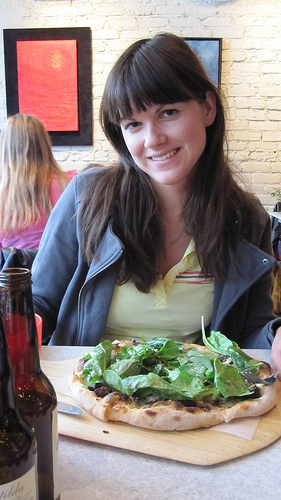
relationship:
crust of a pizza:
[69, 337, 276, 435] [68, 336, 277, 431]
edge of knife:
[56, 400, 82, 410] [54, 399, 84, 417]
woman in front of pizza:
[27, 27, 279, 372] [68, 336, 277, 431]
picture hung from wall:
[1, 25, 96, 152] [1, 0, 279, 220]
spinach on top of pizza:
[81, 315, 277, 404] [68, 336, 277, 431]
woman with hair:
[27, 27, 279, 372] [74, 33, 250, 296]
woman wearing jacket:
[27, 27, 279, 372] [29, 166, 280, 352]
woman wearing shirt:
[27, 27, 279, 372] [98, 230, 215, 346]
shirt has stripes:
[98, 230, 215, 346] [170, 264, 214, 286]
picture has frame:
[1, 25, 96, 152] [1, 26, 97, 148]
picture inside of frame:
[182, 36, 222, 94] [176, 36, 222, 93]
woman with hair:
[3, 110, 79, 256] [1, 111, 67, 229]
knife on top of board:
[54, 399, 84, 417] [40, 345, 279, 467]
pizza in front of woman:
[68, 336, 277, 431] [27, 27, 279, 372]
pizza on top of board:
[68, 336, 277, 431] [40, 345, 279, 467]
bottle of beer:
[2, 265, 60, 499] [16, 391, 60, 500]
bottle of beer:
[0, 318, 38, 499] [1, 406, 43, 500]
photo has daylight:
[1, 0, 280, 499] [0, 1, 280, 214]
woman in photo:
[27, 27, 279, 372] [1, 0, 280, 499]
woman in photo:
[3, 110, 79, 256] [1, 0, 280, 499]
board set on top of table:
[40, 345, 279, 467] [36, 341, 280, 498]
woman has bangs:
[27, 27, 279, 372] [108, 51, 193, 121]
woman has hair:
[27, 27, 279, 372] [74, 33, 250, 296]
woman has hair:
[3, 110, 79, 256] [1, 111, 67, 229]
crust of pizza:
[69, 337, 276, 435] [68, 336, 277, 431]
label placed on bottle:
[48, 399, 63, 500] [2, 265, 60, 499]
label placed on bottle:
[2, 463, 38, 499] [0, 318, 38, 499]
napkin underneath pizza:
[57, 363, 263, 439] [68, 336, 277, 431]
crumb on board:
[99, 428, 111, 436] [40, 345, 279, 467]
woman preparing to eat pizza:
[27, 27, 279, 372] [68, 336, 277, 431]